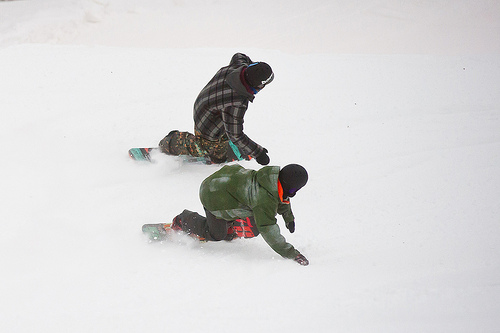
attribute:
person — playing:
[162, 163, 312, 253]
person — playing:
[183, 52, 273, 168]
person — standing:
[177, 49, 277, 169]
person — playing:
[161, 52, 273, 162]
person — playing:
[171, 163, 301, 257]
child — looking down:
[158, 50, 276, 166]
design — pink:
[230, 216, 255, 239]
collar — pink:
[273, 177, 290, 204]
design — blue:
[228, 137, 245, 161]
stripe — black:
[192, 93, 243, 123]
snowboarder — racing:
[156, 51, 276, 164]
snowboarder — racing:
[169, 160, 310, 267]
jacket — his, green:
[202, 166, 288, 252]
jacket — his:
[168, 73, 270, 158]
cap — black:
[271, 157, 316, 210]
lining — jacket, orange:
[273, 186, 289, 206]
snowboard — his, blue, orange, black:
[127, 140, 267, 166]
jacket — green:
[192, 160, 283, 240]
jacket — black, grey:
[183, 61, 256, 155]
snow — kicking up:
[141, 213, 222, 271]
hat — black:
[276, 157, 312, 200]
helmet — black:
[231, 58, 289, 88]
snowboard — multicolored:
[114, 136, 300, 163]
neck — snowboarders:
[264, 173, 299, 208]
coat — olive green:
[192, 167, 283, 229]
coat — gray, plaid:
[179, 54, 266, 150]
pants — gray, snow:
[177, 201, 252, 275]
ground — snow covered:
[0, 68, 499, 327]